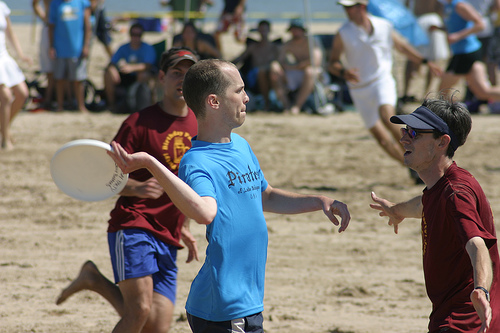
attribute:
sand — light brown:
[4, 105, 496, 330]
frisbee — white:
[44, 137, 131, 206]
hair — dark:
[178, 55, 236, 117]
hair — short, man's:
[423, 84, 475, 156]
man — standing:
[95, 17, 245, 204]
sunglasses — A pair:
[399, 125, 442, 138]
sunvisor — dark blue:
[392, 105, 452, 135]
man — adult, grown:
[368, 97, 498, 331]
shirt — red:
[112, 98, 195, 252]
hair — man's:
[424, 92, 472, 146]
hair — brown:
[184, 60, 215, 104]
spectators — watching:
[19, 5, 476, 160]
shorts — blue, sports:
[105, 231, 182, 301]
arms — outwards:
[393, 190, 494, 295]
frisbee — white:
[48, 139, 124, 201]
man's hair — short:
[182, 61, 221, 116]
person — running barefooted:
[55, 46, 199, 331]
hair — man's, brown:
[185, 48, 239, 120]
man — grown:
[172, 55, 272, 322]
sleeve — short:
[184, 161, 214, 208]